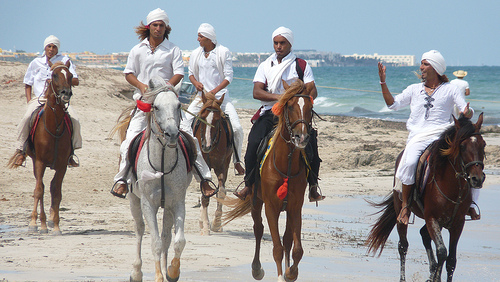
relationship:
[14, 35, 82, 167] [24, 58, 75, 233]
man riding horse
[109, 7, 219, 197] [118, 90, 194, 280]
man riding horse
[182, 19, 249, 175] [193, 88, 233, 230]
man riding horse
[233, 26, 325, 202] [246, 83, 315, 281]
man riding horse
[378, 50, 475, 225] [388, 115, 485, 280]
lady riding horse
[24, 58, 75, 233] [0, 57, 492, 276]
horse on a beach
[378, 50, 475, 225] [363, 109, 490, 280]
lady riding horse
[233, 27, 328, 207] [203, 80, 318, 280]
man riding horse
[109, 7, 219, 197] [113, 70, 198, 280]
man riding horse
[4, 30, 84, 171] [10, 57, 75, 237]
man riding horse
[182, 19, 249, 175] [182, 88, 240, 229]
man riding horse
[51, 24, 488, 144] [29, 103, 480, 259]
people on horses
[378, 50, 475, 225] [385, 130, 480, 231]
lady on horse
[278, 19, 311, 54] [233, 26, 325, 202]
turban on man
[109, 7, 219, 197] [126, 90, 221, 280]
man on horse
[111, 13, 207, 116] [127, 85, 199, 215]
man on horse